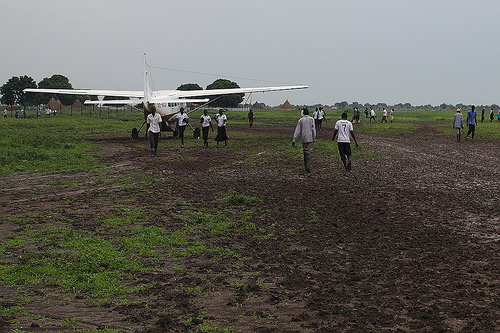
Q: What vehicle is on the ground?
A: Airplane.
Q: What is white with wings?
A: Airplane.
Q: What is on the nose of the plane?
A: Propeller.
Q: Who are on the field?
A: A group of people.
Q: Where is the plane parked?
A: On the field.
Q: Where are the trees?
A: Behind the plane.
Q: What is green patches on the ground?
A: Grass.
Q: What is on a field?
A: Mud.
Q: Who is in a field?
A: A man.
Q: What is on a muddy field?
A: A plane.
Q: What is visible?
A: A plane.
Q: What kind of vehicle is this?
A: Airplane.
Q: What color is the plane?
A: White.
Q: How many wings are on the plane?
A: Two.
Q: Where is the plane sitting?
A: Field.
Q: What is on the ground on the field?
A: Dirt and grass.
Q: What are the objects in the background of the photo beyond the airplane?
A: Trees.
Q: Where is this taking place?
A: Airfield.